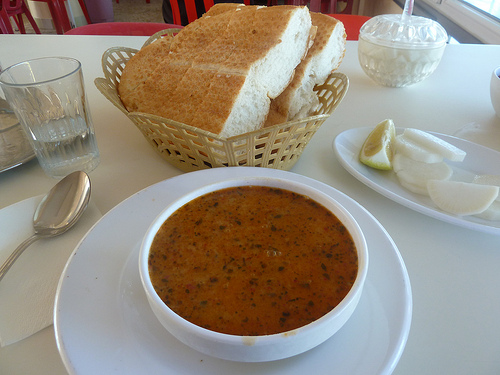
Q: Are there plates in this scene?
A: Yes, there is a plate.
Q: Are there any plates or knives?
A: Yes, there is a plate.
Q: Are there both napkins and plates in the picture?
A: Yes, there are both a plate and a napkin.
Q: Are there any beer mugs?
A: No, there are no beer mugs.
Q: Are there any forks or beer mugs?
A: No, there are no beer mugs or forks.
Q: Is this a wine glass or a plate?
A: This is a plate.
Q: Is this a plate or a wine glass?
A: This is a plate.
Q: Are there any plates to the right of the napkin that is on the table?
A: Yes, there is a plate to the right of the napkin.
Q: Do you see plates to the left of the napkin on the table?
A: No, the plate is to the right of the napkin.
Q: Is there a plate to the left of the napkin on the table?
A: No, the plate is to the right of the napkin.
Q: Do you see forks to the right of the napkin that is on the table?
A: No, there is a plate to the right of the napkin.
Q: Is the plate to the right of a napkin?
A: Yes, the plate is to the right of a napkin.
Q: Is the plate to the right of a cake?
A: No, the plate is to the right of a napkin.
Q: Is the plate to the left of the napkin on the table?
A: No, the plate is to the right of the napkin.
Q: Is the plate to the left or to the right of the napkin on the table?
A: The plate is to the right of the napkin.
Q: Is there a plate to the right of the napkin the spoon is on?
A: Yes, there is a plate to the right of the napkin.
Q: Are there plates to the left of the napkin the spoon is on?
A: No, the plate is to the right of the napkin.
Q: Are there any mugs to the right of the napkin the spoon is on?
A: No, there is a plate to the right of the napkin.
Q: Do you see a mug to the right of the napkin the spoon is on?
A: No, there is a plate to the right of the napkin.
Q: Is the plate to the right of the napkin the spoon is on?
A: Yes, the plate is to the right of the napkin.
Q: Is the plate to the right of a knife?
A: No, the plate is to the right of the napkin.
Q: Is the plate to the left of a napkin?
A: No, the plate is to the right of a napkin.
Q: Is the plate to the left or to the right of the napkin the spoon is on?
A: The plate is to the right of the napkin.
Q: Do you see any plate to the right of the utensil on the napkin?
A: Yes, there is a plate to the right of the spoon.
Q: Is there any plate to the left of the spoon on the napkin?
A: No, the plate is to the right of the spoon.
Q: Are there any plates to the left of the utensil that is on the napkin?
A: No, the plate is to the right of the spoon.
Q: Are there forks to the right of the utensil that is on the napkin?
A: No, there is a plate to the right of the spoon.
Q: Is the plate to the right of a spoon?
A: Yes, the plate is to the right of a spoon.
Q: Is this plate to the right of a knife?
A: No, the plate is to the right of a spoon.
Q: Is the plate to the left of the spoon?
A: No, the plate is to the right of the spoon.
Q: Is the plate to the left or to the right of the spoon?
A: The plate is to the right of the spoon.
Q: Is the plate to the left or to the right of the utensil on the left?
A: The plate is to the right of the spoon.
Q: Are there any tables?
A: Yes, there is a table.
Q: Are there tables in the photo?
A: Yes, there is a table.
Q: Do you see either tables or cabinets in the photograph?
A: Yes, there is a table.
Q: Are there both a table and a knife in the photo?
A: No, there is a table but no knives.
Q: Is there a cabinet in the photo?
A: No, there are no cabinets.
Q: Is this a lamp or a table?
A: This is a table.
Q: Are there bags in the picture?
A: No, there are no bags.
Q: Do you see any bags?
A: No, there are no bags.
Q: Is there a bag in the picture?
A: No, there are no bags.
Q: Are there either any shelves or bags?
A: No, there are no bags or shelves.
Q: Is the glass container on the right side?
A: Yes, the container is on the right of the image.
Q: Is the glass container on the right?
A: Yes, the container is on the right of the image.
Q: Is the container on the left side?
A: No, the container is on the right of the image.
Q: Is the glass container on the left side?
A: No, the container is on the right of the image.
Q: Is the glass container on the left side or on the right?
A: The container is on the right of the image.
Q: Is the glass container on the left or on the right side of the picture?
A: The container is on the right of the image.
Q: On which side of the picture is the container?
A: The container is on the right of the image.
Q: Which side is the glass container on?
A: The container is on the right of the image.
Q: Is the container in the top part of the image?
A: Yes, the container is in the top of the image.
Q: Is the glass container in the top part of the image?
A: Yes, the container is in the top of the image.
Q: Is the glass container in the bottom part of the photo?
A: No, the container is in the top of the image.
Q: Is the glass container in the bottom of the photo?
A: No, the container is in the top of the image.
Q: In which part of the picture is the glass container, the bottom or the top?
A: The container is in the top of the image.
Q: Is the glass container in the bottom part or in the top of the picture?
A: The container is in the top of the image.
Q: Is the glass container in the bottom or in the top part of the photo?
A: The container is in the top of the image.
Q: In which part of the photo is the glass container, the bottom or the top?
A: The container is in the top of the image.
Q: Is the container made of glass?
A: Yes, the container is made of glass.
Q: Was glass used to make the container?
A: Yes, the container is made of glass.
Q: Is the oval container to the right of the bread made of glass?
A: Yes, the container is made of glass.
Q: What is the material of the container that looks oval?
A: The container is made of glass.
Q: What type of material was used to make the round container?
A: The container is made of glass.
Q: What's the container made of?
A: The container is made of glass.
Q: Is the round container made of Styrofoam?
A: No, the container is made of glass.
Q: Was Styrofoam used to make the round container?
A: No, the container is made of glass.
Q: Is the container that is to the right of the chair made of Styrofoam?
A: No, the container is made of glass.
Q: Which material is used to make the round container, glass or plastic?
A: The container is made of glass.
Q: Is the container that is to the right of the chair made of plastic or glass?
A: The container is made of glass.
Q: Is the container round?
A: Yes, the container is round.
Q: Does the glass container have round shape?
A: Yes, the container is round.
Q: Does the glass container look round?
A: Yes, the container is round.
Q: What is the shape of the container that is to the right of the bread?
A: The container is round.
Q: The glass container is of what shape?
A: The container is round.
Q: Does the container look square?
A: No, the container is round.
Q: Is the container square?
A: No, the container is round.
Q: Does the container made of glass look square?
A: No, the container is round.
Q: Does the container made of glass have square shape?
A: No, the container is round.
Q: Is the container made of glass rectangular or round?
A: The container is round.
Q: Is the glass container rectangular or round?
A: The container is round.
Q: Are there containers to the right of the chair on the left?
A: Yes, there is a container to the right of the chair.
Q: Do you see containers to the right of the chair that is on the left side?
A: Yes, there is a container to the right of the chair.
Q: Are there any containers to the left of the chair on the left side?
A: No, the container is to the right of the chair.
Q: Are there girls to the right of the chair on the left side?
A: No, there is a container to the right of the chair.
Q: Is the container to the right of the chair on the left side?
A: Yes, the container is to the right of the chair.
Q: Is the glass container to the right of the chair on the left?
A: Yes, the container is to the right of the chair.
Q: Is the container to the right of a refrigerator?
A: No, the container is to the right of the chair.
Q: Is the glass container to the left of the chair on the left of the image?
A: No, the container is to the right of the chair.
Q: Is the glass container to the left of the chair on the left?
A: No, the container is to the right of the chair.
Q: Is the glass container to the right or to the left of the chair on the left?
A: The container is to the right of the chair.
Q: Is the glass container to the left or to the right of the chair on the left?
A: The container is to the right of the chair.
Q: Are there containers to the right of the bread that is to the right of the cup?
A: Yes, there is a container to the right of the bread.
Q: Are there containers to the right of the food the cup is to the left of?
A: Yes, there is a container to the right of the bread.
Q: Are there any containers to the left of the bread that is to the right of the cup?
A: No, the container is to the right of the bread.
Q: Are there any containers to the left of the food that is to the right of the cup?
A: No, the container is to the right of the bread.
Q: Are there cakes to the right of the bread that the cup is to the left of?
A: No, there is a container to the right of the bread.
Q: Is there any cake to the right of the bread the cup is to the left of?
A: No, there is a container to the right of the bread.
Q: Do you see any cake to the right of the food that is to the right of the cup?
A: No, there is a container to the right of the bread.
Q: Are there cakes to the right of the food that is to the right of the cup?
A: No, there is a container to the right of the bread.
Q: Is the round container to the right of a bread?
A: Yes, the container is to the right of a bread.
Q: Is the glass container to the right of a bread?
A: Yes, the container is to the right of a bread.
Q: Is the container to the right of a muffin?
A: No, the container is to the right of a bread.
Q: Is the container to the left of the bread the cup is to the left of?
A: No, the container is to the right of the bread.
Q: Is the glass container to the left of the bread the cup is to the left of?
A: No, the container is to the right of the bread.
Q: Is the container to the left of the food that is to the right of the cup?
A: No, the container is to the right of the bread.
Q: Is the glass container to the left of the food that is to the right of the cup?
A: No, the container is to the right of the bread.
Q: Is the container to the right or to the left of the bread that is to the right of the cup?
A: The container is to the right of the bread.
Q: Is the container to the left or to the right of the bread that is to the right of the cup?
A: The container is to the right of the bread.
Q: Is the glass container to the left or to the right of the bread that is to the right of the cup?
A: The container is to the right of the bread.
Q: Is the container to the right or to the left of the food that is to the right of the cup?
A: The container is to the right of the bread.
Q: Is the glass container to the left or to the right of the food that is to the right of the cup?
A: The container is to the right of the bread.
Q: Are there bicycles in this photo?
A: No, there are no bicycles.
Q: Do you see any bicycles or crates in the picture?
A: No, there are no bicycles or crates.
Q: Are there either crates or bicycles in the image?
A: No, there are no bicycles or crates.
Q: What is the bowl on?
A: The bowl is on the table.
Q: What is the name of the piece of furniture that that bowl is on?
A: The piece of furniture is a table.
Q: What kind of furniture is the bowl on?
A: The bowl is on the table.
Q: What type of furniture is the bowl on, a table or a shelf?
A: The bowl is on a table.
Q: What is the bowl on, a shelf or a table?
A: The bowl is on a table.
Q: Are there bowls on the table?
A: Yes, there is a bowl on the table.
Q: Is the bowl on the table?
A: Yes, the bowl is on the table.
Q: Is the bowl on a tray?
A: No, the bowl is on the table.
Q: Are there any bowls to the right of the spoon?
A: Yes, there is a bowl to the right of the spoon.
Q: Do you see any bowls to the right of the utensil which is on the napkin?
A: Yes, there is a bowl to the right of the spoon.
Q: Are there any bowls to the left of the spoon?
A: No, the bowl is to the right of the spoon.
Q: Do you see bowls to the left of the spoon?
A: No, the bowl is to the right of the spoon.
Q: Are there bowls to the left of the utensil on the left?
A: No, the bowl is to the right of the spoon.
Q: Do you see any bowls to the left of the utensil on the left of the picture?
A: No, the bowl is to the right of the spoon.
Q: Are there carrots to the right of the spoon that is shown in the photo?
A: No, there is a bowl to the right of the spoon.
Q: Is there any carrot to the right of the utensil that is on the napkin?
A: No, there is a bowl to the right of the spoon.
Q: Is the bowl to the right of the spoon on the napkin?
A: Yes, the bowl is to the right of the spoon.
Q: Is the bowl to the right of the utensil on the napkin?
A: Yes, the bowl is to the right of the spoon.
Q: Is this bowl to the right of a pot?
A: No, the bowl is to the right of the spoon.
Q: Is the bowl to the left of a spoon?
A: No, the bowl is to the right of a spoon.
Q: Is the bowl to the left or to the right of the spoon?
A: The bowl is to the right of the spoon.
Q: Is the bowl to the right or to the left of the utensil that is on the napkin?
A: The bowl is to the right of the spoon.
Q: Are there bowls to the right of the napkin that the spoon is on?
A: Yes, there is a bowl to the right of the napkin.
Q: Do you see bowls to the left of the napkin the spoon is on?
A: No, the bowl is to the right of the napkin.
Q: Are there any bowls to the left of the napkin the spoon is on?
A: No, the bowl is to the right of the napkin.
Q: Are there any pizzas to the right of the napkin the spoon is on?
A: No, there is a bowl to the right of the napkin.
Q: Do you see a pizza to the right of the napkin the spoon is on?
A: No, there is a bowl to the right of the napkin.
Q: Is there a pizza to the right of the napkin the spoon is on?
A: No, there is a bowl to the right of the napkin.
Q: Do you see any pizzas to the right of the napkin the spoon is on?
A: No, there is a bowl to the right of the napkin.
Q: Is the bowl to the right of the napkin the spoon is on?
A: Yes, the bowl is to the right of the napkin.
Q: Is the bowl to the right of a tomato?
A: No, the bowl is to the right of the napkin.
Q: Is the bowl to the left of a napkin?
A: No, the bowl is to the right of a napkin.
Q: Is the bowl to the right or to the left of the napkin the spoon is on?
A: The bowl is to the right of the napkin.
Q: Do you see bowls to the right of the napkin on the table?
A: Yes, there is a bowl to the right of the napkin.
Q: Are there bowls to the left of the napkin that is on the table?
A: No, the bowl is to the right of the napkin.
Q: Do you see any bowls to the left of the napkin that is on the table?
A: No, the bowl is to the right of the napkin.